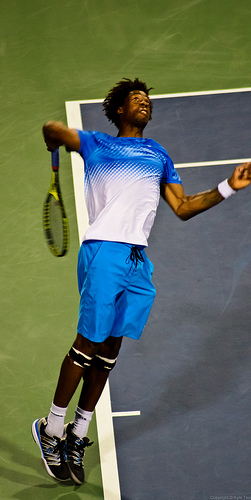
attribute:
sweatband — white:
[213, 181, 234, 198]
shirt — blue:
[70, 135, 183, 219]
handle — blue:
[50, 146, 59, 171]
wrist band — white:
[217, 180, 235, 202]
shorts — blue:
[67, 222, 158, 344]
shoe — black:
[31, 416, 70, 481]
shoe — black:
[61, 420, 93, 484]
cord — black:
[127, 245, 145, 269]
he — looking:
[29, 76, 250, 486]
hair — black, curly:
[99, 77, 155, 125]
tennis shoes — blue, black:
[29, 414, 94, 488]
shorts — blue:
[70, 239, 149, 340]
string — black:
[126, 243, 145, 276]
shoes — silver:
[26, 413, 93, 489]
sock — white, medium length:
[63, 398, 98, 485]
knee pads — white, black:
[62, 343, 124, 373]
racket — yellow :
[43, 183, 62, 206]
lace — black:
[76, 443, 85, 474]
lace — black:
[48, 440, 68, 470]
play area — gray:
[64, 87, 248, 499]